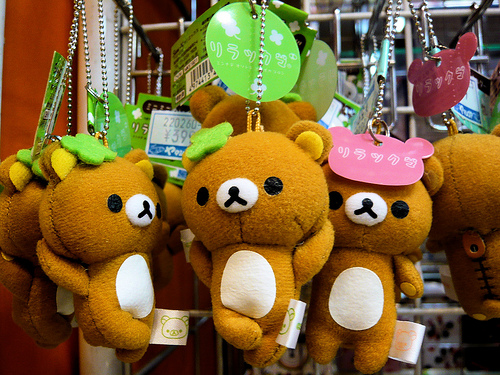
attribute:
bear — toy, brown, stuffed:
[180, 118, 331, 363]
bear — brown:
[17, 126, 173, 363]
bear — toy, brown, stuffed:
[43, 164, 194, 368]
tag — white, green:
[141, 306, 190, 346]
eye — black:
[260, 172, 285, 197]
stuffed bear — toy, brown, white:
[182, 123, 337, 354]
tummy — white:
[216, 249, 277, 318]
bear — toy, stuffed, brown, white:
[297, 160, 413, 372]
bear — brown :
[145, 112, 359, 350]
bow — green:
[60, 133, 117, 165]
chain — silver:
[243, 2, 264, 115]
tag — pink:
[409, 32, 476, 117]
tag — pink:
[321, 121, 434, 191]